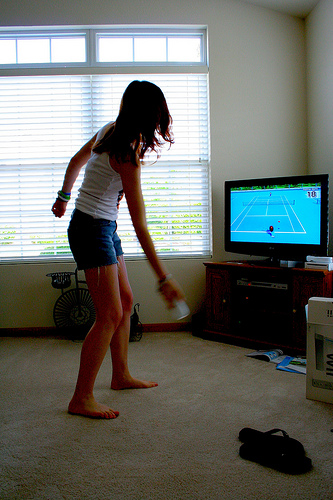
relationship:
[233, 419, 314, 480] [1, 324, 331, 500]
flip flops on floor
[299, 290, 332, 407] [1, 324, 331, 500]
box on floor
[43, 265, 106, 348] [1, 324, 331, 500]
decoration on floor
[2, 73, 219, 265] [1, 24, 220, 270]
blinds on windows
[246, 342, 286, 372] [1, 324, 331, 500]
book on floor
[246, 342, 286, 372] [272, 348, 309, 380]
book with papers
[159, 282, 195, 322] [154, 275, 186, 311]
handle in hand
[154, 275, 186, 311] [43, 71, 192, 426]
hand of girl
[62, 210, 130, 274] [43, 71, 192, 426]
short of girl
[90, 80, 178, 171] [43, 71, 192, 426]
hair of girl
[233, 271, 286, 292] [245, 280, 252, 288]
dvd player with light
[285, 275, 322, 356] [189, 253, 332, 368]
door of console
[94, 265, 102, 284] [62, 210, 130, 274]
fringe on short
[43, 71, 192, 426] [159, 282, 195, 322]
girl holding handle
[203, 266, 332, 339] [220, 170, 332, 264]
console next to television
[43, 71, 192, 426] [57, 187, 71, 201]
girl wearing bracelets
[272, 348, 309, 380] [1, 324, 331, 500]
papers on floor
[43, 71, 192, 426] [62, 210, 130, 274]
girl wearing short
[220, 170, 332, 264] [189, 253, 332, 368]
television on console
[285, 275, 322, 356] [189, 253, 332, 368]
door on console